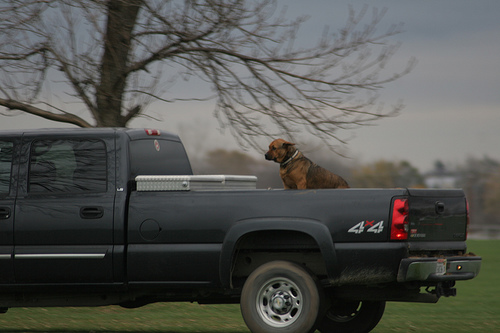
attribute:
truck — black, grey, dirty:
[1, 123, 484, 332]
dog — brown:
[263, 139, 350, 187]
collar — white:
[280, 150, 300, 166]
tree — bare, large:
[1, 0, 415, 154]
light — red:
[386, 196, 411, 243]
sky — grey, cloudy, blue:
[392, 1, 499, 162]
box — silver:
[137, 171, 260, 196]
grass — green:
[388, 240, 500, 332]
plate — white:
[433, 258, 448, 275]